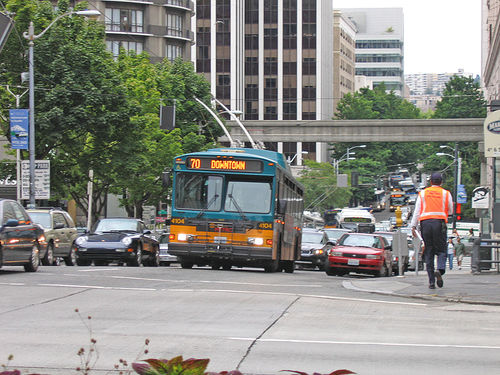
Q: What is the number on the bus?
A: 70.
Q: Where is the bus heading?
A: Downtown.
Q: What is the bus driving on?
A: A cement road.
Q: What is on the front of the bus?
A: A bike rack.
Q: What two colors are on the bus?
A: Blue and orange.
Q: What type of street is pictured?
A: A one-way street.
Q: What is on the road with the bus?
A: Vehicles.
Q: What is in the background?
A: Tall buildings.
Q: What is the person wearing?
A: Vest.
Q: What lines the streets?
A: Buildings.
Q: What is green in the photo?
A: Leaves.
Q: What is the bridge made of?
A: Cement.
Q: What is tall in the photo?
A: Buildings.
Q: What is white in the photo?
A: Lines.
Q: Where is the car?
A: By the bus.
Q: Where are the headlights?
A: On the front of the bus.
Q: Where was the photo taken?
A: Near a city street.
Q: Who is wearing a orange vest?
A: Man walking.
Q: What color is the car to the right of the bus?
A: Red.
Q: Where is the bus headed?
A: Downtown.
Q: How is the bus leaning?
A: To right.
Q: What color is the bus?
A: Orange and blue.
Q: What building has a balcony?
A: Left behind trees.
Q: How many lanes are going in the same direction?
A: 4.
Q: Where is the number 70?
A: Top bus.